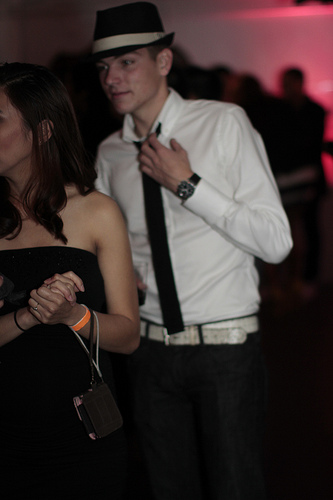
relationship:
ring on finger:
[31, 302, 41, 313] [25, 296, 46, 316]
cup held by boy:
[132, 259, 148, 305] [90, 0, 295, 498]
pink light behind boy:
[1, 1, 333, 309] [90, 0, 295, 498]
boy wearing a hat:
[90, 0, 295, 498] [83, 2, 175, 62]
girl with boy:
[0, 61, 143, 495] [90, 0, 295, 498]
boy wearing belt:
[90, 0, 295, 498] [136, 315, 259, 345]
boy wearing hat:
[90, 0, 295, 498] [83, 2, 175, 62]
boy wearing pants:
[90, 0, 295, 498] [133, 312, 269, 498]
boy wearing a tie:
[90, 0, 295, 498] [132, 119, 184, 333]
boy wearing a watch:
[90, 0, 295, 498] [176, 174, 201, 202]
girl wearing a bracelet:
[0, 61, 143, 495] [69, 303, 92, 331]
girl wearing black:
[0, 61, 143, 495] [0, 245, 127, 496]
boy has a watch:
[90, 0, 295, 498] [176, 174, 201, 202]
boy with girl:
[90, 0, 295, 498] [0, 61, 143, 495]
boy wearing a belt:
[90, 0, 295, 498] [136, 315, 259, 345]